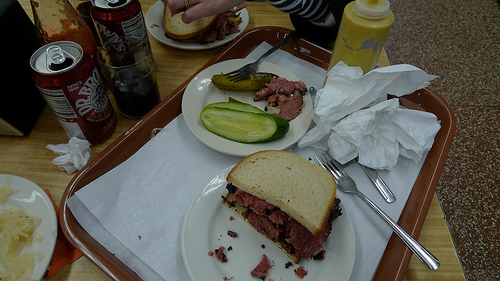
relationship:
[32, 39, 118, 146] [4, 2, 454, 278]
bottle on table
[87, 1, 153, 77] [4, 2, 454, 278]
can on table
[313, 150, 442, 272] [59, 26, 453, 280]
fork on tray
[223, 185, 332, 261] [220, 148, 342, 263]
meat on sandwich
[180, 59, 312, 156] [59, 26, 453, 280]
plate on tray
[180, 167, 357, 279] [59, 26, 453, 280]
plate on tray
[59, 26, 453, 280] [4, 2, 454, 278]
tray on table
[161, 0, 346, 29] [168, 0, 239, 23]
human being has hand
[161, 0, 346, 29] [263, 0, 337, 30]
human being has arm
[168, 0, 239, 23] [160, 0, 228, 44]
hand on sandwich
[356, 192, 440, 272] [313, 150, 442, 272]
handle on fork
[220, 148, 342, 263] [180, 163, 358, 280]
sandwich on dish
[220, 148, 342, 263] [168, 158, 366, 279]
sandwich on dish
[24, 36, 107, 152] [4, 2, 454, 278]
soda on table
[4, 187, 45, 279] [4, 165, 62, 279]
food on plate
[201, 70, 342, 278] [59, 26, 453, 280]
dishes on tray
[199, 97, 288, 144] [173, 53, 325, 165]
pickle on plate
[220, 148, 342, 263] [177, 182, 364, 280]
sandwich on plate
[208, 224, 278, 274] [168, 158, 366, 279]
crambs on dish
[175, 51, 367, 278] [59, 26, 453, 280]
dishes on tray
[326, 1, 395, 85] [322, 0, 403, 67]
bottle has mustard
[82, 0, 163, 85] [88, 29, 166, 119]
drink next glass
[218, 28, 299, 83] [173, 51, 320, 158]
fork next dish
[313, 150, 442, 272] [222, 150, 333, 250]
fork next to sandwich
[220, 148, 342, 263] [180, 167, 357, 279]
sandwich on plate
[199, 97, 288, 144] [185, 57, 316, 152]
pickle on plate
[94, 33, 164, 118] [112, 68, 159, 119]
glass with beverage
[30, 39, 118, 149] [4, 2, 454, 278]
coke on table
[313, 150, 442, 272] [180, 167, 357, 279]
fork next to plate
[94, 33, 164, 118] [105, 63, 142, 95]
glass with ice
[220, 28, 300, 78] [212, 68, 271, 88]
fork on pickle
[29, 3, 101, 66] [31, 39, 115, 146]
bottle behind soda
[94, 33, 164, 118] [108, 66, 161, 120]
glass containing beverage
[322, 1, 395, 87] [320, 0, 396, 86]
bottle containing mustard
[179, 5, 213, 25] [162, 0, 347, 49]
finger belonging to human being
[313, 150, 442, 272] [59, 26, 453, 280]
fork lying on top of tray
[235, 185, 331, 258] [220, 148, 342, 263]
meat placed in sandwich